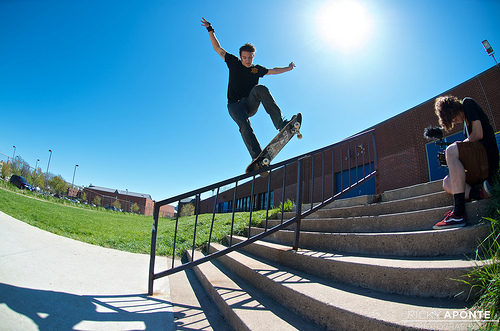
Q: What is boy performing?
A: Tricks.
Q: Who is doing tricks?
A: Young man.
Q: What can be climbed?
A: Stairs.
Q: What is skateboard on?
A: Railing.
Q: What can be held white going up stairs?
A: Railing.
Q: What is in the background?
A: Brick building.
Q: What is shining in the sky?
A: The sun.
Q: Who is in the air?
A: A skateboarder.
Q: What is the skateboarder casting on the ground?
A: A shadow.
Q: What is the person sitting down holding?
A: A camera.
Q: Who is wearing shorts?
A: The cameraperson.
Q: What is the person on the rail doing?
A: Skateboarding.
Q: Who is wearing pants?
A: The skater.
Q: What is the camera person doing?
A: Sitting.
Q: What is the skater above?
A: The rail.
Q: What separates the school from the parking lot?
A: A fence.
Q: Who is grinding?
A: The skateboarder.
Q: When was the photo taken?
A: Daylight hours.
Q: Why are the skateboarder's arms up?
A: For balance.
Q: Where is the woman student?
A: On top of the stairs.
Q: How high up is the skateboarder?
A: Halfway up the stairs.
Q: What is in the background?
A: A brick building.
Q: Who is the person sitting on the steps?
A: Possibly a friend of the skateboarder.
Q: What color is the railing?
A: Blue.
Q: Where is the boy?
A: Air.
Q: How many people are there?
A: Two.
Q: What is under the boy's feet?
A: Skateboard.